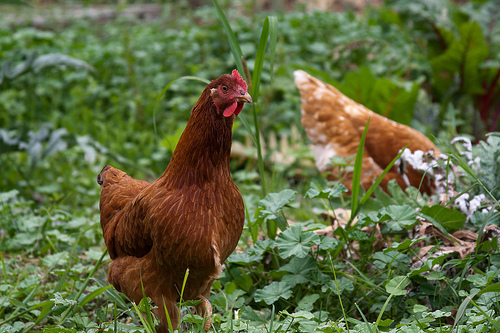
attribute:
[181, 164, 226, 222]
feathers — brown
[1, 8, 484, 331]
grass — green, long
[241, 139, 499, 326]
plants — small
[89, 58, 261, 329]
hen — standing, dark brown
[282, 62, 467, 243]
hen — tan, white, bent over, light brown, feeding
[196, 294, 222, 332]
claw — raised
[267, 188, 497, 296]
leaves — green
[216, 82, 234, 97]
eye — open